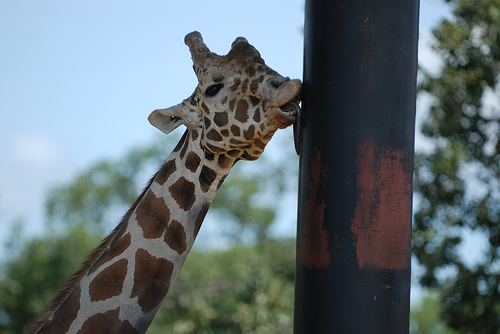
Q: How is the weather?
A: It is clear.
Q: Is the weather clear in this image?
A: Yes, it is clear.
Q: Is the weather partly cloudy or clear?
A: It is clear.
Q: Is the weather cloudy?
A: No, it is clear.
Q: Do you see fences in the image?
A: No, there are no fences.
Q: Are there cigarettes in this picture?
A: No, there are no cigarettes.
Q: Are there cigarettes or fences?
A: No, there are no cigarettes or fences.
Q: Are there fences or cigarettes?
A: No, there are no cigarettes or fences.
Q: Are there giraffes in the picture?
A: Yes, there is a giraffe.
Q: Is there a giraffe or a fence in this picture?
A: Yes, there is a giraffe.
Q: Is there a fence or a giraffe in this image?
A: Yes, there is a giraffe.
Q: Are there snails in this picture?
A: No, there are no snails.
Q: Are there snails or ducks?
A: No, there are no snails or ducks.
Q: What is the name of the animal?
A: The animal is a giraffe.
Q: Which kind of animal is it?
A: The animal is a giraffe.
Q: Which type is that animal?
A: This is a giraffe.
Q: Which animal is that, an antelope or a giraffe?
A: This is a giraffe.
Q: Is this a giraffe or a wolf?
A: This is a giraffe.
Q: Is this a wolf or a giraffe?
A: This is a giraffe.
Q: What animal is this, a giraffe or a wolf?
A: This is a giraffe.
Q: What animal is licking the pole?
A: The giraffe is licking the pole.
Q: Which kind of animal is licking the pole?
A: The animal is a giraffe.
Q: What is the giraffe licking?
A: The giraffe is licking the pole.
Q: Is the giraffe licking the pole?
A: Yes, the giraffe is licking the pole.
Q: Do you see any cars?
A: No, there are no cars.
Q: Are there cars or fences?
A: No, there are no cars or fences.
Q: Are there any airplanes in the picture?
A: No, there are no airplanes.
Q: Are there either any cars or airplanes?
A: No, there are no airplanes or cars.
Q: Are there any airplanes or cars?
A: No, there are no airplanes or cars.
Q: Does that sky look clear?
A: Yes, the sky is clear.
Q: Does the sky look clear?
A: Yes, the sky is clear.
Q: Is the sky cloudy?
A: No, the sky is clear.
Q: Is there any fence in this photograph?
A: No, there are no fences.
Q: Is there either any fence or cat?
A: No, there are no fences or cats.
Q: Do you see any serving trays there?
A: No, there are no serving trays.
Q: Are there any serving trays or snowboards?
A: No, there are no serving trays or snowboards.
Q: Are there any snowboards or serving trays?
A: No, there are no serving trays or snowboards.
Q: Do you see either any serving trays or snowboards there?
A: No, there are no serving trays or snowboards.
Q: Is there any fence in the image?
A: No, there are no fences.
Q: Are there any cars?
A: No, there are no cars.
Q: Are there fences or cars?
A: No, there are no cars or fences.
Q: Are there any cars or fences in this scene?
A: No, there are no cars or fences.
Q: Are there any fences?
A: No, there are no fences.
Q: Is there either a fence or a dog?
A: No, there are no fences or dogs.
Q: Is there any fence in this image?
A: No, there are no fences.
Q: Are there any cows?
A: No, there are no cows.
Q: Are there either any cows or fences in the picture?
A: No, there are no cows or fences.